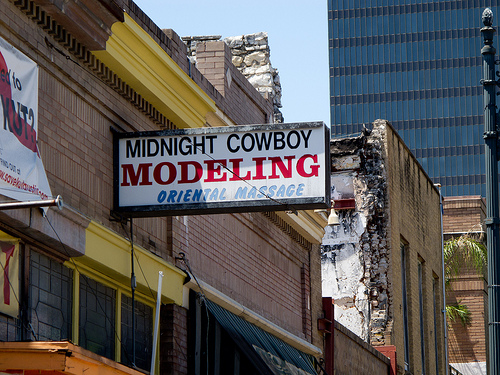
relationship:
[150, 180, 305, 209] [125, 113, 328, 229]
writing on sign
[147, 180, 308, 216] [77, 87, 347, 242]
writing on sign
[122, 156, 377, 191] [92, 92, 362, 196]
writing on sign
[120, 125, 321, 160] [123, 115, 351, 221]
writing on sign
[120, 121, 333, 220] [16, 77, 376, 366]
sign on building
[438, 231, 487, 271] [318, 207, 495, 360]
tree behind building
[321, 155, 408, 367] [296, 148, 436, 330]
wall on building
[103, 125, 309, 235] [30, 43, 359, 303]
sign on building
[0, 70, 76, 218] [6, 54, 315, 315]
banner on wall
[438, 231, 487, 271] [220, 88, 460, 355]
tree by buildings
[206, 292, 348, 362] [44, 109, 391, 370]
awning on building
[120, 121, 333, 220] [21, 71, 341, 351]
sign on building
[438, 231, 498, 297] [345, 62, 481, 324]
tree by building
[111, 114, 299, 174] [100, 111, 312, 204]
writing on sign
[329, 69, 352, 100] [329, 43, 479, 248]
window on building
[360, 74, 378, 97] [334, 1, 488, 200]
window on high rise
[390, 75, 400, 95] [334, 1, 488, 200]
window on high rise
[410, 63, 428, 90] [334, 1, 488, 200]
window on high rise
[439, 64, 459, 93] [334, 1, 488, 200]
window on high rise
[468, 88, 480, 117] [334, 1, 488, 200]
window on high rise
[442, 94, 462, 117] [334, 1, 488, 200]
window on high rise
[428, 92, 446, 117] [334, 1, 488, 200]
window on high rise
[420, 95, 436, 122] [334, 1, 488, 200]
window on high rise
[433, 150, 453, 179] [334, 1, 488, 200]
window on high rise